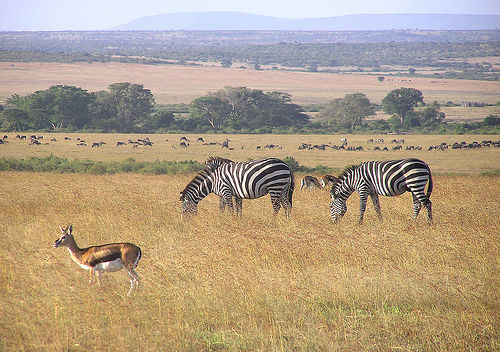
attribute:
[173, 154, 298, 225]
zebra — grazing, white, black, fat, feeding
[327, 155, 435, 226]
zebra — grazing, white, black, feeding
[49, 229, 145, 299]
antelope — here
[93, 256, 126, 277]
belly — white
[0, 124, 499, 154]
herd — animals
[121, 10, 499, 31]
mountain — hazy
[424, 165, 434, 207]
tail — black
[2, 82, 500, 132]
trees — green, far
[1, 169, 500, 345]
grass — brown, dead, long, dry, dried, tall, here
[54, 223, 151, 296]
deer — standing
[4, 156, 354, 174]
bush — green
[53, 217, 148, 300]
gazelle — small, white, brown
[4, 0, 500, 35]
sky — blue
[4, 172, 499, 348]
weeds — brown, dead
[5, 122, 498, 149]
herd — animals, grazing, large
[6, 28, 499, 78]
forest — here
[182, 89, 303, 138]
tree — green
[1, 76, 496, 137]
bushes — dividing, green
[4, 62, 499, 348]
fields — open